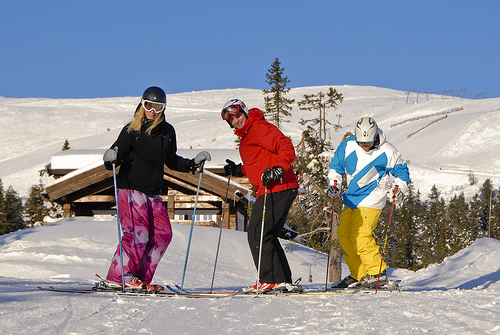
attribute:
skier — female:
[97, 87, 212, 294]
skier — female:
[326, 117, 408, 289]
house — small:
[42, 135, 270, 237]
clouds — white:
[147, 27, 328, 65]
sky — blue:
[3, 2, 498, 95]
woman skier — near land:
[95, 85, 209, 290]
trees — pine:
[389, 182, 480, 264]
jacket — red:
[233, 105, 297, 190]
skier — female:
[221, 96, 297, 282]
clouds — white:
[341, 42, 371, 64]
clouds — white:
[323, 31, 376, 61]